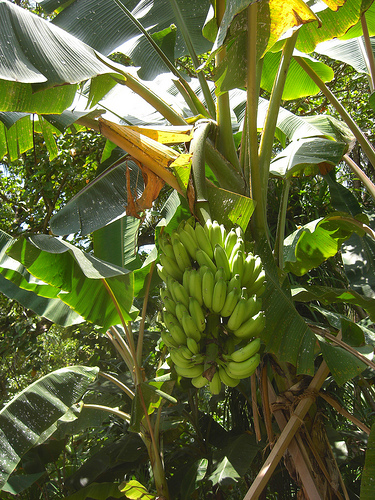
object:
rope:
[290, 407, 306, 426]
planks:
[258, 372, 287, 428]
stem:
[149, 449, 172, 496]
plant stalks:
[151, 49, 317, 269]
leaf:
[1, 0, 190, 126]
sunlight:
[70, 65, 188, 126]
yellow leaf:
[81, 108, 196, 221]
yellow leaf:
[313, 413, 333, 487]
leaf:
[211, 0, 268, 94]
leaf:
[48, 144, 161, 240]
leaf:
[256, 104, 362, 181]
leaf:
[271, 201, 374, 297]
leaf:
[0, 362, 103, 485]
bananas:
[155, 217, 266, 395]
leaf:
[5, 232, 142, 334]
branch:
[171, 110, 214, 219]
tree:
[0, 293, 58, 401]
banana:
[151, 218, 265, 391]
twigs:
[41, 193, 55, 234]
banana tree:
[55, 22, 334, 457]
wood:
[298, 350, 340, 419]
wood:
[241, 447, 277, 498]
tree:
[293, 50, 375, 133]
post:
[245, 363, 327, 498]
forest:
[0, 125, 123, 396]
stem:
[200, 324, 217, 408]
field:
[0, 33, 374, 498]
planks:
[284, 437, 320, 497]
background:
[81, 427, 241, 500]